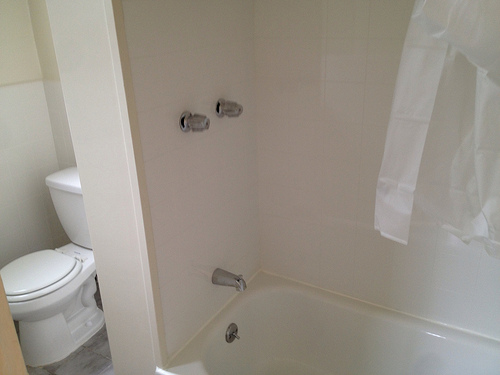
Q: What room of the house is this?
A: Bathroom.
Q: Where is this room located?
A: House.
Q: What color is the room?
A: White.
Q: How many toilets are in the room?
A: One.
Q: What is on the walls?
A: Tile.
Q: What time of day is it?
A: Daytime.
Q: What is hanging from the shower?
A: Shower curtain.